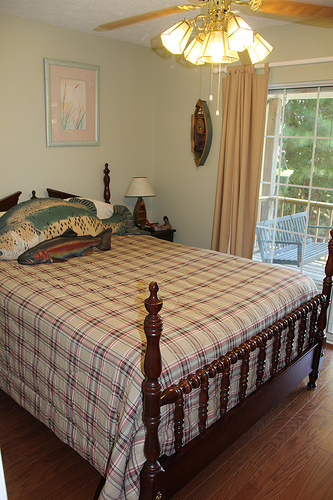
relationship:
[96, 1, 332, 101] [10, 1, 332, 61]
celing fan on ceiling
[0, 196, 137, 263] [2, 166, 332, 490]
pillows on bed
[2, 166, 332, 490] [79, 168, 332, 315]
bed has post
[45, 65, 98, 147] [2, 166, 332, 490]
picture above bed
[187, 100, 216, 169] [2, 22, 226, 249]
boat decor on wall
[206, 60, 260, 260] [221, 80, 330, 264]
curtains on window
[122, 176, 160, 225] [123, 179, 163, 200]
lamp has shade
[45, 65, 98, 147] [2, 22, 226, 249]
picture on wall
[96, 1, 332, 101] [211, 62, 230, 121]
celing fan has strings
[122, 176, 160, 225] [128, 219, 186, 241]
lamp on nightstand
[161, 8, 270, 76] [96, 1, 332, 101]
lights on celing fan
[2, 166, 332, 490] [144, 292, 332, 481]
bed has slats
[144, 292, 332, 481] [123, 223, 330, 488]
slats on foot portian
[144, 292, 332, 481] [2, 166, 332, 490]
slats on bed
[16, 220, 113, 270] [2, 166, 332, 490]
fish on bed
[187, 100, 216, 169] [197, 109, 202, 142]
boat decor has fish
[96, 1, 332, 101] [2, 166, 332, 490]
celing fan above bed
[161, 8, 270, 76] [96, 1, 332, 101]
lights below celing fan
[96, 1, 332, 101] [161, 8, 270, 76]
celing fan and lights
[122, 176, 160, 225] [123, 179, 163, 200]
lamp and shade